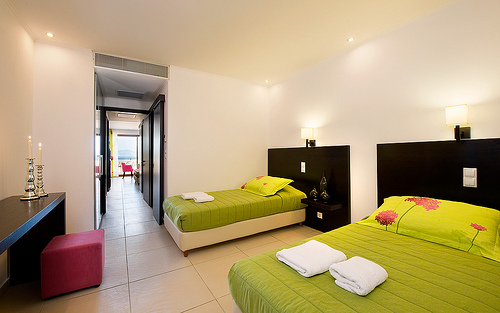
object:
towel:
[181, 191, 214, 202]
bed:
[161, 175, 307, 256]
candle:
[19, 135, 40, 201]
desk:
[0, 190, 73, 310]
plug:
[300, 161, 305, 173]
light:
[445, 104, 469, 141]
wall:
[339, 46, 482, 99]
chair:
[121, 162, 134, 177]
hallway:
[96, 73, 166, 232]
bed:
[226, 195, 500, 311]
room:
[0, 0, 496, 310]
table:
[300, 188, 351, 234]